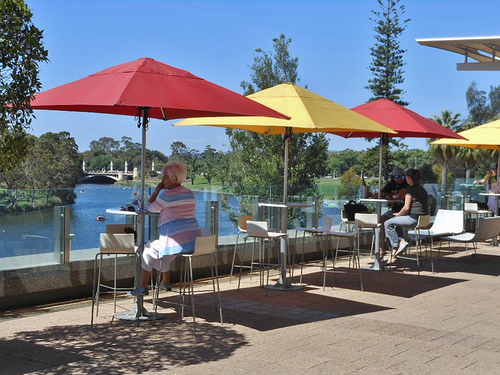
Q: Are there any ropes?
A: No, there are no ropes.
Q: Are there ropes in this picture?
A: No, there are no ropes.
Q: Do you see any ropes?
A: No, there are no ropes.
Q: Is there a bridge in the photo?
A: Yes, there is a bridge.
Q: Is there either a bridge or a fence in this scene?
A: Yes, there is a bridge.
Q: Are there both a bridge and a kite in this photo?
A: No, there is a bridge but no kites.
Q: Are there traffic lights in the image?
A: No, there are no traffic lights.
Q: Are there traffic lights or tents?
A: No, there are no traffic lights or tents.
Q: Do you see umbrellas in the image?
A: Yes, there is an umbrella.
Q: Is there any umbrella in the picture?
A: Yes, there is an umbrella.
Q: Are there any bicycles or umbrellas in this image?
A: Yes, there is an umbrella.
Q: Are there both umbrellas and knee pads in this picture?
A: No, there is an umbrella but no knee pads.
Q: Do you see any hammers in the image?
A: No, there are no hammers.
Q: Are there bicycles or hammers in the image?
A: No, there are no hammers or bicycles.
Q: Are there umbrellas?
A: Yes, there is an umbrella.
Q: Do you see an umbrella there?
A: Yes, there is an umbrella.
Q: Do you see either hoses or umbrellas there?
A: Yes, there is an umbrella.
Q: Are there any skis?
A: No, there are no skis.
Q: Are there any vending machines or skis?
A: No, there are no skis or vending machines.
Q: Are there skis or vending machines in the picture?
A: No, there are no skis or vending machines.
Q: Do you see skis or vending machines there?
A: No, there are no skis or vending machines.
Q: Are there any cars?
A: No, there are no cars.